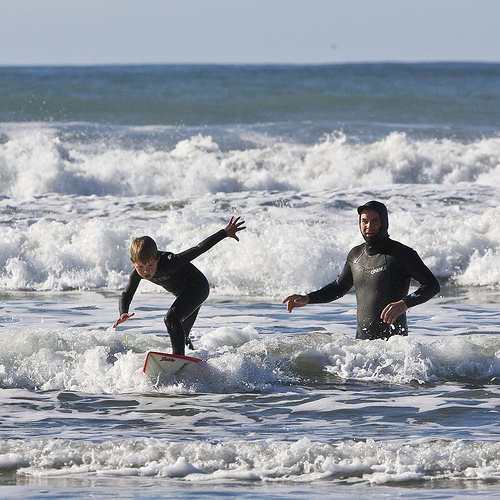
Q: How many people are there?
A: Two.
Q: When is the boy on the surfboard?
A: Daytime.